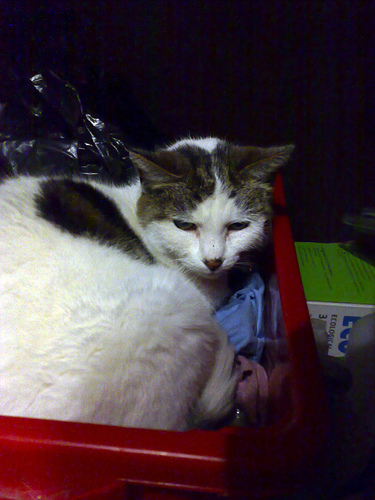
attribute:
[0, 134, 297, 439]
cat — here, white, laying, brown, big, ended, spotted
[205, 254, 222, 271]
nose — brown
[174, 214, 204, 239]
eye — opened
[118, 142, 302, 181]
ears — brown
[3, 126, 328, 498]
box — red, blue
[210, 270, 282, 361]
cloth — blue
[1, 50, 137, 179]
bag — black, plastic, blue